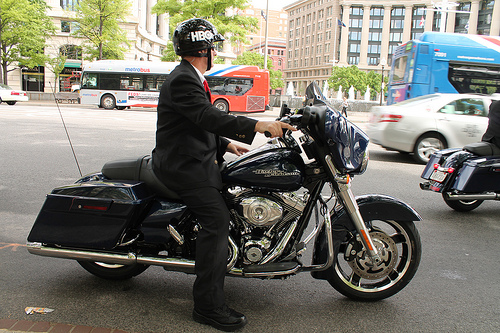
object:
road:
[5, 104, 155, 209]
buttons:
[235, 132, 246, 138]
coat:
[151, 59, 261, 192]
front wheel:
[324, 216, 421, 302]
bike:
[24, 82, 421, 303]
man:
[148, 21, 293, 333]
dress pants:
[152, 155, 230, 312]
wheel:
[98, 92, 118, 108]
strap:
[200, 46, 210, 71]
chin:
[208, 58, 213, 68]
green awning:
[59, 59, 84, 69]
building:
[0, 0, 171, 100]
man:
[484, 79, 499, 148]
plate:
[428, 165, 449, 180]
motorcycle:
[419, 139, 498, 211]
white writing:
[187, 29, 213, 45]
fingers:
[281, 119, 296, 131]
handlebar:
[262, 100, 305, 138]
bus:
[77, 60, 269, 115]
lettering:
[190, 29, 213, 41]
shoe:
[188, 298, 248, 331]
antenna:
[47, 80, 86, 177]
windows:
[368, 18, 379, 60]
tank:
[224, 143, 306, 192]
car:
[364, 91, 500, 166]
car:
[0, 82, 30, 106]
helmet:
[173, 18, 225, 72]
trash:
[24, 303, 57, 318]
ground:
[0, 103, 499, 332]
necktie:
[203, 78, 216, 105]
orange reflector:
[359, 226, 373, 252]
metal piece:
[338, 184, 382, 264]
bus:
[383, 22, 499, 106]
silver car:
[360, 81, 483, 166]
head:
[181, 18, 217, 71]